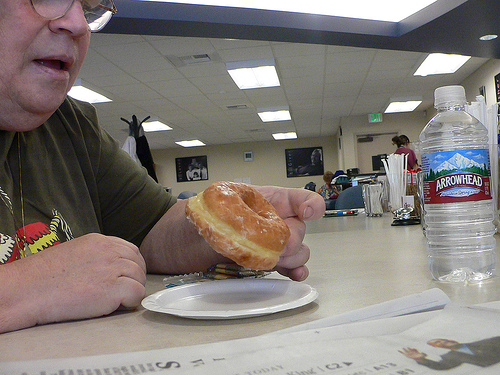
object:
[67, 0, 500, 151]
ceiling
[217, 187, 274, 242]
glaze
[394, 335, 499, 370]
person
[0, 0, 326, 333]
person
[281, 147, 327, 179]
poster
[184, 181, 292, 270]
glazed doughnut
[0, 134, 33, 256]
necklace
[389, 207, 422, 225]
bell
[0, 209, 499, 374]
counter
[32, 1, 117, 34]
eyeglasses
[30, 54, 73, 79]
mouth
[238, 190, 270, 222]
hole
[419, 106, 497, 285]
water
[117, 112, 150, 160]
coat rack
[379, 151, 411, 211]
straws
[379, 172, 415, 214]
cup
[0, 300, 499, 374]
newspaper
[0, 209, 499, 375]
table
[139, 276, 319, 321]
plate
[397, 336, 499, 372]
image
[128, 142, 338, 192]
wall